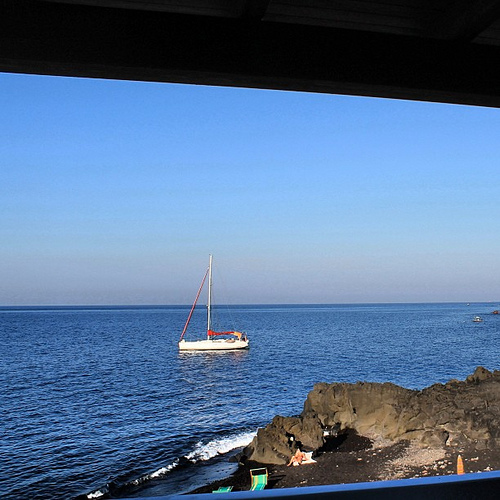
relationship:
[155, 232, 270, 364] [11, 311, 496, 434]
boat on water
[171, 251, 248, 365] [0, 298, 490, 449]
boat on water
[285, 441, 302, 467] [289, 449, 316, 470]
person on towel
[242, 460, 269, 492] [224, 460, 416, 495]
beach chair on soil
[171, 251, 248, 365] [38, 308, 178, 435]
boat in water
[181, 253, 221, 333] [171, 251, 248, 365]
mast on boat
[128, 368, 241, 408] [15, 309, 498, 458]
ripples in water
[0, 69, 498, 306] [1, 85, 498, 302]
white clouds in blue sky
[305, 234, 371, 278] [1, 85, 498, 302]
white clouds in blue sky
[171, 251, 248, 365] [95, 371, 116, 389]
boat in ocean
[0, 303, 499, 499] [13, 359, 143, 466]
ripples in water